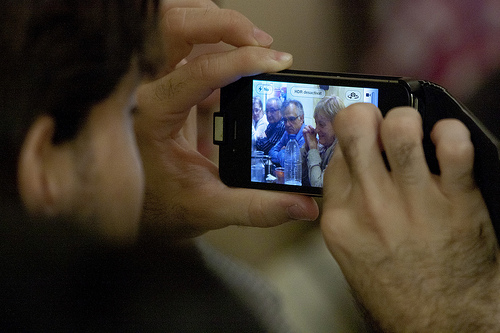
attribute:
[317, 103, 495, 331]
right hand — one, male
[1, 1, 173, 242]
man — one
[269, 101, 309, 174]
man — one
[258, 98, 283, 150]
man — one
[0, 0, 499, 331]
man — one, fun-loving